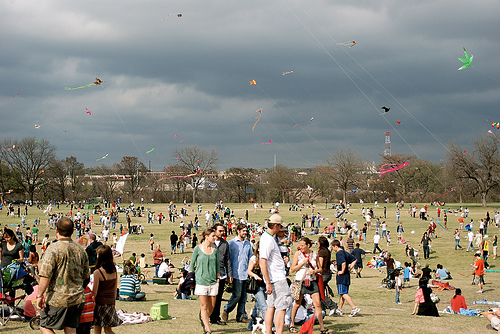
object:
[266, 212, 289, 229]
cap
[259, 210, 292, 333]
man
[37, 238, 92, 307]
shirt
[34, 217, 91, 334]
man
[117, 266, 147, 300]
woman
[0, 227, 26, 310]
woman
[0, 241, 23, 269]
shirt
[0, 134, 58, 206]
tree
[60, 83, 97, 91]
tail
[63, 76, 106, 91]
kite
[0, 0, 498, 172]
sky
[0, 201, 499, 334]
field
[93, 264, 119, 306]
shirt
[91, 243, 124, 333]
girl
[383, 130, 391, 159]
tower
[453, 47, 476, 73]
kite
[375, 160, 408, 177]
kite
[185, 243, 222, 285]
shirt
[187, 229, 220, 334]
woman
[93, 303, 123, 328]
skirt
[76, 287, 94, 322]
shirt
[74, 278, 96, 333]
boy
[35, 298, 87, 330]
pants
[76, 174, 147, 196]
buildings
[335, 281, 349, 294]
shorts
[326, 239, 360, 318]
man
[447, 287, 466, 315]
people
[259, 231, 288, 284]
shirt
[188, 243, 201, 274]
sleeves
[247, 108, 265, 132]
kites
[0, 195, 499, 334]
crowd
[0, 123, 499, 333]
park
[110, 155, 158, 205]
trees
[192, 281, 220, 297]
shorts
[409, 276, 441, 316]
woman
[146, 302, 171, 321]
cooler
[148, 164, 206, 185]
kite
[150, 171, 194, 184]
tail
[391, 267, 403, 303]
kid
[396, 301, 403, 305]
sneakers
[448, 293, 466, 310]
shirt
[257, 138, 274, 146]
kite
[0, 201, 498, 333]
grass